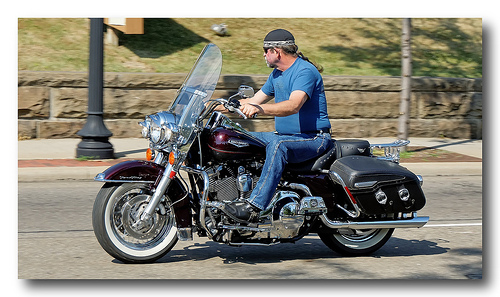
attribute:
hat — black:
[260, 29, 304, 48]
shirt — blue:
[259, 69, 344, 137]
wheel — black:
[97, 170, 186, 264]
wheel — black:
[326, 190, 399, 257]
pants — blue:
[249, 129, 332, 204]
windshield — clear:
[164, 45, 225, 137]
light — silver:
[150, 112, 166, 144]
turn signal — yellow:
[165, 152, 187, 171]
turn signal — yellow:
[139, 142, 158, 160]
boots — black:
[225, 197, 261, 217]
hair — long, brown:
[291, 46, 327, 73]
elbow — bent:
[281, 91, 306, 120]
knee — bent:
[264, 135, 303, 169]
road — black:
[32, 173, 475, 277]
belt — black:
[301, 127, 337, 136]